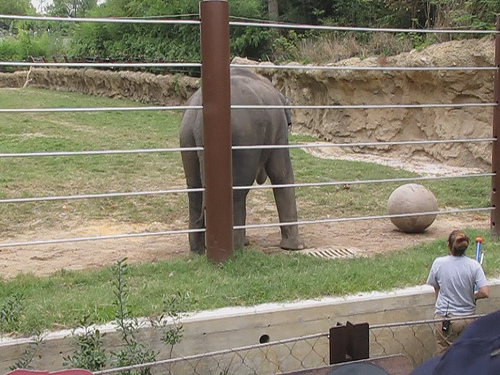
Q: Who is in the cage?
A: An elephant.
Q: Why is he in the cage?
A: To keep him safe.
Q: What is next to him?
A: A ball.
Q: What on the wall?
A: Grass.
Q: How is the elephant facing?
A: His back to the camera.